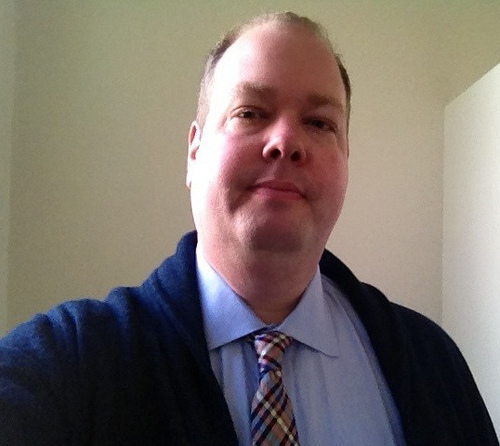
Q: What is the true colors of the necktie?
A: Blue, brown, peach, and white.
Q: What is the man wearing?
A: A cardigan sweater.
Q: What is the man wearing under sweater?
A: A dress shirt.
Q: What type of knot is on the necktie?
A: Windsor.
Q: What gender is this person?
A: A male.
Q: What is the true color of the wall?
A: White.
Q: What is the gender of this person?
A: Male.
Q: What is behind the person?
A: A wall.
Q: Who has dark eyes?
A: The man.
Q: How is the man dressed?
A: Business casual.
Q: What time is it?
A: Afternoon.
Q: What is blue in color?
A: Shirt.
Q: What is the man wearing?
A: A tie.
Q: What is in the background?
A: A wall.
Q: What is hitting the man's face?
A: Light.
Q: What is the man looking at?
A: The camera.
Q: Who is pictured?
A: A Man.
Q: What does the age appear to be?
A: Middle aged.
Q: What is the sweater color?
A: Blue.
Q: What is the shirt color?
A: Blue.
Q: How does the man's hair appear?
A: Thinning.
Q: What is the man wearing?
A: Jacket and shirt.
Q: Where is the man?
A: In a room.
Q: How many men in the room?
A: One.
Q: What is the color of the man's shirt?
A: Blue.